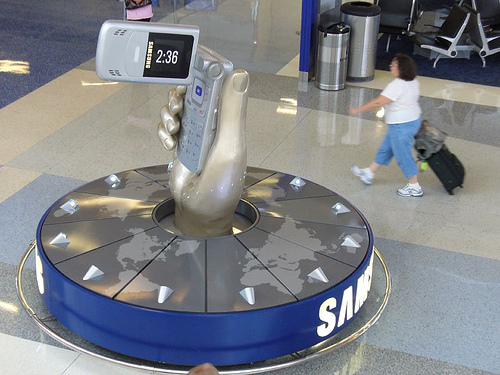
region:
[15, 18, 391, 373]
a samsung cellular phone display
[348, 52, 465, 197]
a lady pulling a backpack on wheels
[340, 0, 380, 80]
a silver and black trash receptical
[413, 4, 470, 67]
silver and black seats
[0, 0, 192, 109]
blue carpet next to the samsung display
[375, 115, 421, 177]
the lady is wearing blue pants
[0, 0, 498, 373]
the floor is tiled with gray, blue and beige tile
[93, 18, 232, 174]
The cellular phone display time is 2:36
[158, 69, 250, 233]
a display of a right hand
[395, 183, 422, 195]
the lady is wearing white and blue sneakers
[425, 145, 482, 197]
black luggage with wheels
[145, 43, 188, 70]
large white letters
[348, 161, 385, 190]
woman's white sneaker with blue stripes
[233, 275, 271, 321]
small white and blue sundial sign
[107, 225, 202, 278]
gray world map on sundial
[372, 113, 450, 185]
woman wearing blue jeans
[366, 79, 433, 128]
woman wearing short sleeve white shirt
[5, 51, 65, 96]
broad lines on gray floor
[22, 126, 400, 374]
round blue and silver object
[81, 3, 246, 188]
large black and silver cell phone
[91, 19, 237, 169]
phone statue held by hand statue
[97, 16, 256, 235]
fake hand statue holding Samsung phone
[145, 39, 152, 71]
Samsung brand of phone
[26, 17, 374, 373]
Samsung phone stand featuring product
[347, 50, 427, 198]
Woman in airport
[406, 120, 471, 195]
suitcase of woman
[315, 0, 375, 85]
a pair of trashcan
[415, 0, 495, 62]
empty seats at the airport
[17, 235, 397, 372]
support for the stand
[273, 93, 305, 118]
light reflection from the ceiling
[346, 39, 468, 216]
woman pulling black suitcase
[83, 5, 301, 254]
large hand holding cell phone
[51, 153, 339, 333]
image of world on clock face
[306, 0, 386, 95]
two silver containers by wall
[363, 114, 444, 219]
woman wearing blue capris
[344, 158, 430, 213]
woman wearing athletic shoes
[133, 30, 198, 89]
time displayed on cell phone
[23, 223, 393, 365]
blue base around world clock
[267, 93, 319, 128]
light reflecting on tile floor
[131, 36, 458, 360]
blue, gray and white tile flooring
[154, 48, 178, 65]
samsung sez it's 2:36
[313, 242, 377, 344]
½ of white samsung on big blue circular thing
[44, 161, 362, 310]
lightbulbs in silver cones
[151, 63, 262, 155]
the unpolished fingernails of a giant silvertone plastic hand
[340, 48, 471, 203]
plump middle aged woman with frizzy hair+suitcase on wheels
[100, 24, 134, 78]
giant fake cellphone's diagonal vents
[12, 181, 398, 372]
big silvertone circle around blue circular stand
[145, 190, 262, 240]
smaller silvertone circle around wrist of huge silvertone plastic hand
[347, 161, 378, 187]
sock+sneaker in motion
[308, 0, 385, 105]
two metal trashcans together